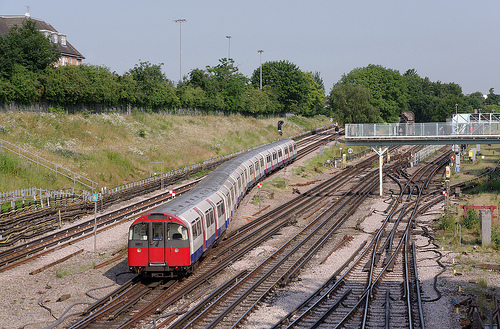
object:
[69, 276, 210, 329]
track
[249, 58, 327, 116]
tree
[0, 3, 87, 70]
house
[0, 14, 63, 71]
tree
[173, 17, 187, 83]
post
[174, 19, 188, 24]
light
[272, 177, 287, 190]
grass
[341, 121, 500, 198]
platform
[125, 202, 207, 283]
car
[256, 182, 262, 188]
flag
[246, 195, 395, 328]
gravel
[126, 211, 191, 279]
front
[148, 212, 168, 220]
sign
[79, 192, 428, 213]
row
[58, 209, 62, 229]
pole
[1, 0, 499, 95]
sky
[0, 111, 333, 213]
hill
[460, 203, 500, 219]
sign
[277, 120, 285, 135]
signal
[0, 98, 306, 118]
fence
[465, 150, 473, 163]
marker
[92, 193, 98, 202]
sign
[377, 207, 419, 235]
intersection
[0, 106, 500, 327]
station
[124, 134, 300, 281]
train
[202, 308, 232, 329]
tracks